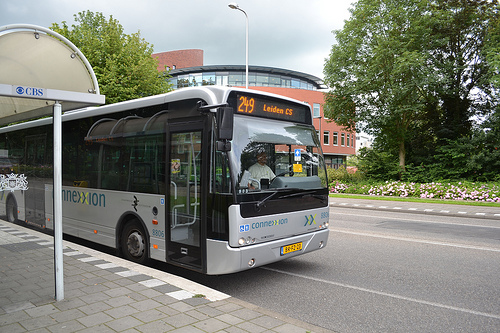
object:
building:
[299, 71, 357, 171]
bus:
[0, 83, 331, 277]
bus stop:
[0, 21, 107, 301]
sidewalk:
[0, 259, 196, 323]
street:
[321, 204, 485, 330]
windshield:
[225, 112, 330, 197]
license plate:
[282, 242, 303, 255]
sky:
[252, 3, 326, 57]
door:
[166, 125, 205, 275]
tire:
[118, 218, 147, 264]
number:
[238, 96, 246, 112]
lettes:
[16, 86, 25, 95]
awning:
[0, 23, 107, 106]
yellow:
[283, 247, 289, 255]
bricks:
[5, 260, 134, 332]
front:
[213, 85, 329, 276]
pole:
[227, 3, 250, 90]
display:
[236, 93, 307, 123]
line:
[304, 276, 495, 321]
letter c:
[25, 86, 31, 95]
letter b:
[31, 87, 38, 96]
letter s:
[38, 88, 45, 96]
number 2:
[236, 92, 246, 112]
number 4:
[242, 96, 250, 112]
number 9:
[248, 98, 255, 114]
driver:
[245, 147, 278, 189]